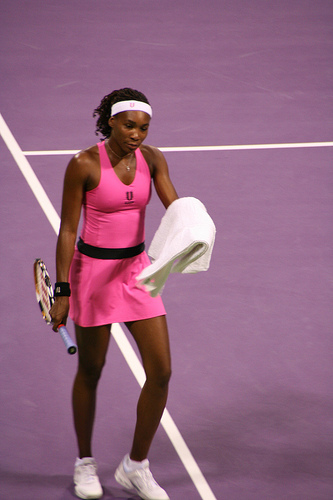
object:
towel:
[136, 196, 218, 298]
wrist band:
[54, 281, 72, 297]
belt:
[77, 236, 146, 259]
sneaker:
[73, 455, 104, 499]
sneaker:
[114, 452, 171, 499]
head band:
[111, 99, 153, 117]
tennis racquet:
[33, 258, 78, 356]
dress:
[69, 141, 168, 328]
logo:
[125, 191, 136, 205]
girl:
[48, 87, 180, 499]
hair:
[93, 87, 150, 140]